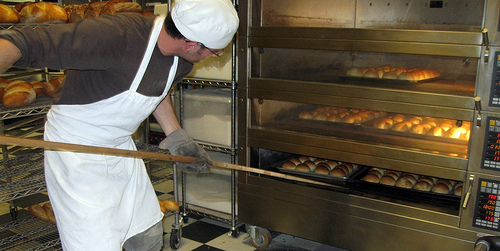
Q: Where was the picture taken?
A: It was taken at the bakery.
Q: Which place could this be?
A: It is a bakery.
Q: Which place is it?
A: It is a bakery.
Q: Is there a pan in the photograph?
A: Yes, there is a pan.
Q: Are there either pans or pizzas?
A: Yes, there is a pan.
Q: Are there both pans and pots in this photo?
A: No, there is a pan but no pots.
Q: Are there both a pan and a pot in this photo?
A: No, there is a pan but no pots.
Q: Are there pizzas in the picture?
A: No, there are no pizzas.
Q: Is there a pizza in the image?
A: No, there are no pizzas.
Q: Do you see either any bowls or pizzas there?
A: No, there are no pizzas or bowls.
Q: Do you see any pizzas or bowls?
A: No, there are no pizzas or bowls.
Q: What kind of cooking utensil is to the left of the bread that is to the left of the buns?
A: The cooking utensil is a pan.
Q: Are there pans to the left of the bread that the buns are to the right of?
A: Yes, there is a pan to the left of the bread.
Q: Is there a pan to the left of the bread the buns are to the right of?
A: Yes, there is a pan to the left of the bread.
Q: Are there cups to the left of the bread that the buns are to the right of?
A: No, there is a pan to the left of the bread.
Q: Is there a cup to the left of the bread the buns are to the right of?
A: No, there is a pan to the left of the bread.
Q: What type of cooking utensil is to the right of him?
A: The cooking utensil is a pan.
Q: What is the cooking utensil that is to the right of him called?
A: The cooking utensil is a pan.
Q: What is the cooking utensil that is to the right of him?
A: The cooking utensil is a pan.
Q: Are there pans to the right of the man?
A: Yes, there is a pan to the right of the man.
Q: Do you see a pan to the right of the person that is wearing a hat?
A: Yes, there is a pan to the right of the man.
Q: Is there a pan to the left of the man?
A: No, the pan is to the right of the man.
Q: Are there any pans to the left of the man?
A: No, the pan is to the right of the man.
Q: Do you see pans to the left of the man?
A: No, the pan is to the right of the man.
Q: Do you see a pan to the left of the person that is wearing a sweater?
A: No, the pan is to the right of the man.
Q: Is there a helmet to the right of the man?
A: No, there is a pan to the right of the man.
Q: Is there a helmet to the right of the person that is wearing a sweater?
A: No, there is a pan to the right of the man.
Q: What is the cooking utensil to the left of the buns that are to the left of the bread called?
A: The cooking utensil is a pan.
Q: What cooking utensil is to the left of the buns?
A: The cooking utensil is a pan.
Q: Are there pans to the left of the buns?
A: Yes, there is a pan to the left of the buns.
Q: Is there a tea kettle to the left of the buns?
A: No, there is a pan to the left of the buns.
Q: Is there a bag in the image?
A: No, there are no bags.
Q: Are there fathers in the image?
A: No, there are no fathers.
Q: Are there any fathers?
A: No, there are no fathers.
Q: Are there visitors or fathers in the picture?
A: No, there are no fathers or visitors.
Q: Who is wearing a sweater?
A: The man is wearing a sweater.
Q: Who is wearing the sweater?
A: The man is wearing a sweater.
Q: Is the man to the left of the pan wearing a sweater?
A: Yes, the man is wearing a sweater.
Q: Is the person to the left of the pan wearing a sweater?
A: Yes, the man is wearing a sweater.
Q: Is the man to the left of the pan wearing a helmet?
A: No, the man is wearing a sweater.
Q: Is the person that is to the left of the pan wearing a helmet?
A: No, the man is wearing a sweater.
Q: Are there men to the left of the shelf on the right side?
A: Yes, there is a man to the left of the shelf.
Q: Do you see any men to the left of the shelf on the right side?
A: Yes, there is a man to the left of the shelf.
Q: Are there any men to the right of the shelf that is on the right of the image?
A: No, the man is to the left of the shelf.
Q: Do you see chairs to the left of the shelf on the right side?
A: No, there is a man to the left of the shelf.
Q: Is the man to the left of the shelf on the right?
A: Yes, the man is to the left of the shelf.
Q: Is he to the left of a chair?
A: No, the man is to the left of the shelf.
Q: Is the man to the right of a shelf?
A: No, the man is to the left of a shelf.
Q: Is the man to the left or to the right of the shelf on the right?
A: The man is to the left of the shelf.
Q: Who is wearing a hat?
A: The man is wearing a hat.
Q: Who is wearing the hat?
A: The man is wearing a hat.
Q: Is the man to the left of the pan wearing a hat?
A: Yes, the man is wearing a hat.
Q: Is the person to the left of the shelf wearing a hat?
A: Yes, the man is wearing a hat.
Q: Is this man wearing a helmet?
A: No, the man is wearing a hat.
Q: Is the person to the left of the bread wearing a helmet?
A: No, the man is wearing a hat.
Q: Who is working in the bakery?
A: The man is working in the bakery.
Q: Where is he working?
A: The man is working in the bakery.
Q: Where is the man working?
A: The man is working in the bakery.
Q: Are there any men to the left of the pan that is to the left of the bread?
A: Yes, there is a man to the left of the pan.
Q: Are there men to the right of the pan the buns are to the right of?
A: No, the man is to the left of the pan.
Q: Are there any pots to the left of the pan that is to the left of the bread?
A: No, there is a man to the left of the pan.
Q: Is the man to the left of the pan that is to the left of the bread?
A: Yes, the man is to the left of the pan.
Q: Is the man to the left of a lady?
A: No, the man is to the left of the pan.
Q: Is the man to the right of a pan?
A: No, the man is to the left of a pan.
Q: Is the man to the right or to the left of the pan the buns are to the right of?
A: The man is to the left of the pan.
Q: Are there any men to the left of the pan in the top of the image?
A: Yes, there is a man to the left of the pan.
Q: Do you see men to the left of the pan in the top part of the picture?
A: Yes, there is a man to the left of the pan.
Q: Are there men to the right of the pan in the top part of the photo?
A: No, the man is to the left of the pan.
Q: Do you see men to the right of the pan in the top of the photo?
A: No, the man is to the left of the pan.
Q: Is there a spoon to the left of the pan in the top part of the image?
A: No, there is a man to the left of the pan.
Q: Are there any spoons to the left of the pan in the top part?
A: No, there is a man to the left of the pan.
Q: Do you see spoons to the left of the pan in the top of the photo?
A: No, there is a man to the left of the pan.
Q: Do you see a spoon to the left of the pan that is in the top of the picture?
A: No, there is a man to the left of the pan.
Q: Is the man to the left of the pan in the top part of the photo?
A: Yes, the man is to the left of the pan.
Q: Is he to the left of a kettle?
A: No, the man is to the left of the pan.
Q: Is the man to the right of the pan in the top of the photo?
A: No, the man is to the left of the pan.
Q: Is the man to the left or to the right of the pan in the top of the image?
A: The man is to the left of the pan.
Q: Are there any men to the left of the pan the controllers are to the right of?
A: Yes, there is a man to the left of the pan.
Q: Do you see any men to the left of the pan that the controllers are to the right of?
A: Yes, there is a man to the left of the pan.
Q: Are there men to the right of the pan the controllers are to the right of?
A: No, the man is to the left of the pan.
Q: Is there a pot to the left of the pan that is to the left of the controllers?
A: No, there is a man to the left of the pan.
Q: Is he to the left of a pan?
A: Yes, the man is to the left of a pan.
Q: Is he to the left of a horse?
A: No, the man is to the left of a pan.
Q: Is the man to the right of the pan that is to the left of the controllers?
A: No, the man is to the left of the pan.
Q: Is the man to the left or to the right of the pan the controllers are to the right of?
A: The man is to the left of the pan.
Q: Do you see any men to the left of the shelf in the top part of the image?
A: Yes, there is a man to the left of the shelf.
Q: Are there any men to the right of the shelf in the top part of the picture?
A: No, the man is to the left of the shelf.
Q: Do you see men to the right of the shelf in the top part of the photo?
A: No, the man is to the left of the shelf.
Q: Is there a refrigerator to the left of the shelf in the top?
A: No, there is a man to the left of the shelf.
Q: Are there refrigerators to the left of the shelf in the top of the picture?
A: No, there is a man to the left of the shelf.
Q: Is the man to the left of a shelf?
A: Yes, the man is to the left of a shelf.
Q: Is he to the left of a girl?
A: No, the man is to the left of a shelf.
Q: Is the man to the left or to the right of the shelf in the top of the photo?
A: The man is to the left of the shelf.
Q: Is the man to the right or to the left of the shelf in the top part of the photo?
A: The man is to the left of the shelf.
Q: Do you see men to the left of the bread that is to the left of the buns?
A: Yes, there is a man to the left of the bread.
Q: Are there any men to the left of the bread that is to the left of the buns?
A: Yes, there is a man to the left of the bread.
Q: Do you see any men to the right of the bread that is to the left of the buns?
A: No, the man is to the left of the bread.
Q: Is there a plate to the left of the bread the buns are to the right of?
A: No, there is a man to the left of the bread.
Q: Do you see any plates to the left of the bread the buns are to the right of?
A: No, there is a man to the left of the bread.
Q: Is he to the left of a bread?
A: Yes, the man is to the left of a bread.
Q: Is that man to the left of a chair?
A: No, the man is to the left of a bread.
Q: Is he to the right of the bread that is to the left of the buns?
A: No, the man is to the left of the bread.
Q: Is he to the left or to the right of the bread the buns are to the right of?
A: The man is to the left of the bread.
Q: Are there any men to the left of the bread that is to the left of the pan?
A: Yes, there is a man to the left of the bread.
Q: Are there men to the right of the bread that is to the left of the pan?
A: No, the man is to the left of the bread.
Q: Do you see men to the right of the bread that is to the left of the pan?
A: No, the man is to the left of the bread.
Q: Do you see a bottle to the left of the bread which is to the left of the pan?
A: No, there is a man to the left of the bread.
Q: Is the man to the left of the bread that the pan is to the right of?
A: Yes, the man is to the left of the bread.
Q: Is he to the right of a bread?
A: No, the man is to the left of a bread.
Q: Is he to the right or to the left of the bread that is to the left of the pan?
A: The man is to the left of the bread.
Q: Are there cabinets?
A: No, there are no cabinets.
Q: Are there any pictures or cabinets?
A: No, there are no cabinets or pictures.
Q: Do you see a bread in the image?
A: Yes, there is a bread.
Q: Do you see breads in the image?
A: Yes, there is a bread.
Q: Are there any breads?
A: Yes, there is a bread.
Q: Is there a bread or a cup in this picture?
A: Yes, there is a bread.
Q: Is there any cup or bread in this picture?
A: Yes, there is a bread.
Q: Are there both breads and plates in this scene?
A: No, there is a bread but no plates.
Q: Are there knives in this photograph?
A: No, there are no knives.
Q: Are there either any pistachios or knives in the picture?
A: No, there are no knives or pistachios.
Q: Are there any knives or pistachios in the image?
A: No, there are no knives or pistachios.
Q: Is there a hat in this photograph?
A: Yes, there is a hat.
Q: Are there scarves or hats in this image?
A: Yes, there is a hat.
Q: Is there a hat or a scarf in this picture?
A: Yes, there is a hat.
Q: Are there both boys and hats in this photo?
A: No, there is a hat but no boys.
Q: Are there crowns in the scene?
A: No, there are no crowns.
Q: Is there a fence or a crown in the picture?
A: No, there are no crowns or fences.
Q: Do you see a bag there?
A: No, there are no bags.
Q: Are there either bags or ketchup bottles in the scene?
A: No, there are no bags or ketchup bottles.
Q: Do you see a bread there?
A: Yes, there is a bread.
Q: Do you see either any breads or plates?
A: Yes, there is a bread.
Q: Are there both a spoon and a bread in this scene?
A: No, there is a bread but no spoons.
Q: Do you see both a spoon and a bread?
A: No, there is a bread but no spoons.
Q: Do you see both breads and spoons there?
A: No, there is a bread but no spoons.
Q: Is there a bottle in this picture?
A: No, there are no bottles.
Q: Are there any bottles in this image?
A: No, there are no bottles.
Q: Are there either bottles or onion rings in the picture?
A: No, there are no bottles or onion rings.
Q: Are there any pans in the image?
A: Yes, there is a pan.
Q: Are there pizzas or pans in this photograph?
A: Yes, there is a pan.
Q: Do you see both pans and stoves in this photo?
A: No, there is a pan but no stoves.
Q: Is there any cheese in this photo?
A: No, there is no cheese.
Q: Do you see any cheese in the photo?
A: No, there is no cheese.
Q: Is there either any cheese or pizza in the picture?
A: No, there are no cheese or pizzas.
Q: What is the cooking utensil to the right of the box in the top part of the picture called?
A: The cooking utensil is a pan.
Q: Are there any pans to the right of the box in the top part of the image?
A: Yes, there is a pan to the right of the box.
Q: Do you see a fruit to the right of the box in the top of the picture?
A: No, there is a pan to the right of the box.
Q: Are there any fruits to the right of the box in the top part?
A: No, there is a pan to the right of the box.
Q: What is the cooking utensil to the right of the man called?
A: The cooking utensil is a pan.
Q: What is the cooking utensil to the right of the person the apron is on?
A: The cooking utensil is a pan.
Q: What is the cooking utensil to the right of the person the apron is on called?
A: The cooking utensil is a pan.